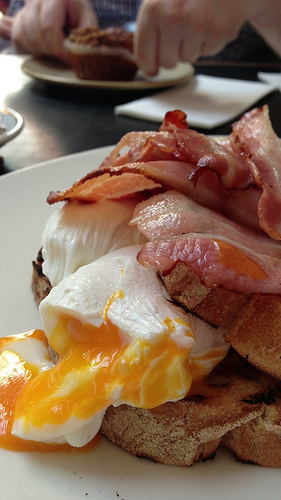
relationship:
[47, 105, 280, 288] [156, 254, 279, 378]
bacon on bread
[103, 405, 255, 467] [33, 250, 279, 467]
crust of bread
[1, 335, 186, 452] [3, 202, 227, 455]
yolk of egg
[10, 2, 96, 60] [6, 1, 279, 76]
hand of a person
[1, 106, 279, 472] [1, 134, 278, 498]
sandwich on plate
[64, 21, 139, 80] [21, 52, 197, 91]
muffin on a plate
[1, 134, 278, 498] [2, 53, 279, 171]
plate on table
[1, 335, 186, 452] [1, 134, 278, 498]
yolk runs on plate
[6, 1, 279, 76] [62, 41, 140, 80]
person removing wrapper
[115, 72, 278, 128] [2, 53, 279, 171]
napkin on table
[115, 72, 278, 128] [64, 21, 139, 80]
napkin by muffin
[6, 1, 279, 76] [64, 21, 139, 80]
person about to eat muffin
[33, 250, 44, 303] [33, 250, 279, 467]
burnt edge of bread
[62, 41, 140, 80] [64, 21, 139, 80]
wrapper of muffin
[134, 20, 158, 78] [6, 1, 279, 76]
finger of person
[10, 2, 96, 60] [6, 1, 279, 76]
hand of person